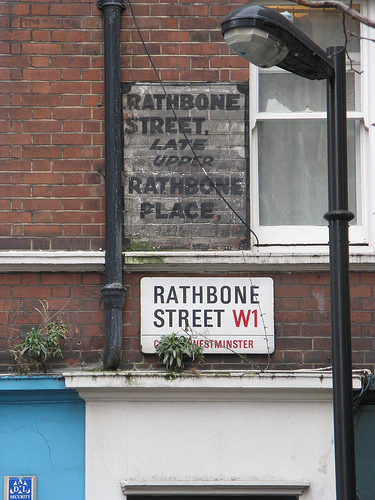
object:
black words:
[153, 283, 260, 303]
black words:
[153, 309, 225, 329]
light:
[220, 0, 331, 85]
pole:
[323, 45, 355, 500]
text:
[122, 86, 245, 223]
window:
[247, 0, 375, 258]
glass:
[222, 30, 291, 68]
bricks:
[0, 1, 250, 259]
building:
[1, 0, 374, 499]